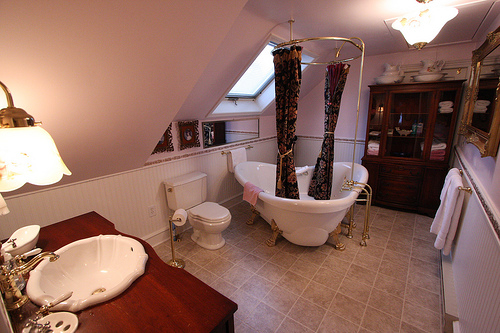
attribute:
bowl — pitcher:
[375, 61, 398, 88]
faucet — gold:
[6, 243, 60, 268]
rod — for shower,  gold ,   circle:
[271, 35, 366, 66]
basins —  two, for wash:
[374, 61, 444, 83]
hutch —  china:
[360, 83, 469, 217]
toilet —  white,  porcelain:
[163, 171, 231, 251]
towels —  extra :
[430, 138, 446, 161]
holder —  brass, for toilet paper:
[167, 207, 187, 227]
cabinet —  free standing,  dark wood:
[361, 82, 461, 217]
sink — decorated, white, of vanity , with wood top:
[19, 235, 154, 315]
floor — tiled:
[147, 202, 444, 332]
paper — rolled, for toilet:
[166, 208, 186, 229]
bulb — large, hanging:
[389, 5, 464, 59]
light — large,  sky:
[226, 46, 312, 105]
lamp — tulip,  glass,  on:
[0, 80, 73, 194]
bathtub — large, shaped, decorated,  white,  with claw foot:
[208, 130, 378, 280]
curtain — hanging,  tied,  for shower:
[300, 62, 356, 201]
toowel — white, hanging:
[429, 165, 462, 262]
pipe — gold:
[359, 191, 370, 245]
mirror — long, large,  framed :
[461, 47, 499, 145]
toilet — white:
[168, 176, 227, 250]